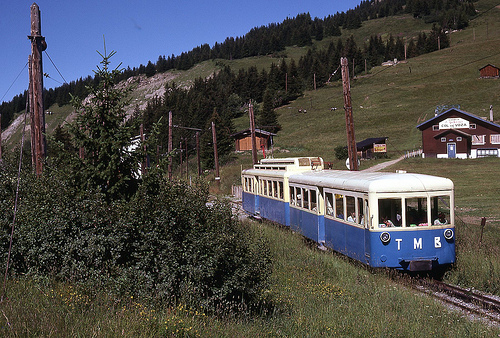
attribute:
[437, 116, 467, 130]
banner — white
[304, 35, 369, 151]
pole — tall, wooden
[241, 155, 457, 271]
train — old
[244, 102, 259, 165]
pole — wooden, tall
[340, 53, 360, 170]
pole — tall, wooden